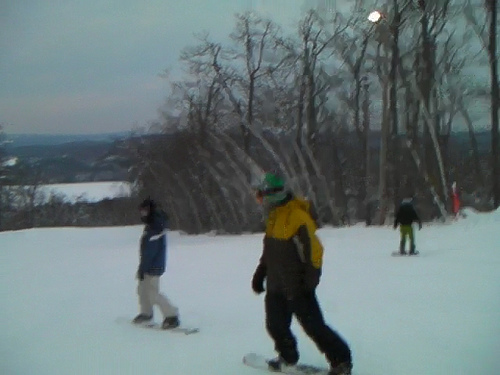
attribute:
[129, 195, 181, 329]
person — skating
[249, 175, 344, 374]
person — skating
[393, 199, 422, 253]
person — skating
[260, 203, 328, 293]
jacket — yellow, black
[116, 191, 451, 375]
snowboarders — active, leading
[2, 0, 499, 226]
trees — behind, curved, dark, dry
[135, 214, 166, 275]
jacket — white, blue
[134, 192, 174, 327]
man — here, skating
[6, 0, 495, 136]
sky — blue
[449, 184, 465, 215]
sign — orange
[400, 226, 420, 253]
pants — green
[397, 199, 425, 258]
man — here, skating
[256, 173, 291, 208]
helmet — green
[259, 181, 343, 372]
man — here, skating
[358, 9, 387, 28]
moon — shining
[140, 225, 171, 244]
stripe — white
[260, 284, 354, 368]
pants — black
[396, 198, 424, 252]
snowboarder — moving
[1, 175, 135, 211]
area — large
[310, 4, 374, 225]
trees — reaching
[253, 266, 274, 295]
glove — black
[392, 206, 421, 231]
jacket — blue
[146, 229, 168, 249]
strip — white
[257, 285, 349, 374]
legs — apart, wide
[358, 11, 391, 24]
light — on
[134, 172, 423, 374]
people — skating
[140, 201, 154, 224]
mask — black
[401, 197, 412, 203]
mask — green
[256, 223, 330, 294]
bottom — black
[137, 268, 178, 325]
pants — white